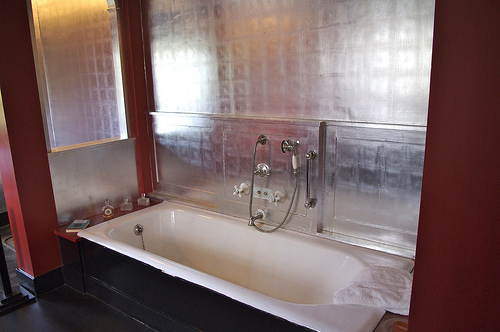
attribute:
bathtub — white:
[66, 155, 406, 332]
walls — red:
[12, 62, 73, 320]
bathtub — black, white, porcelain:
[77, 199, 408, 329]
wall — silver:
[147, 2, 434, 250]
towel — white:
[332, 263, 413, 313]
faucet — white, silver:
[248, 209, 267, 227]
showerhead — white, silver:
[246, 130, 303, 233]